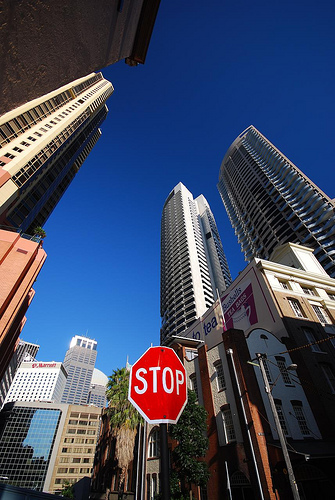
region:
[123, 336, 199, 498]
stop sign on a pole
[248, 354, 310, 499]
street light on a pole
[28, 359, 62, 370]
Marriott building in the background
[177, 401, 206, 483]
green leaves on a tree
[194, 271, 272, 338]
advertisement on a building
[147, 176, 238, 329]
skyscraper in the distance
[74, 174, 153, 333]
bright blue sky in the background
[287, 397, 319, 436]
window of a building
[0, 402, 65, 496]
glass facade of a building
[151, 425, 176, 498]
pole of a stop sign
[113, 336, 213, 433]
red stop sign on street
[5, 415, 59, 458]
reflections from black building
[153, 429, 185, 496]
black pole holding sign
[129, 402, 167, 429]
white lining of stop sign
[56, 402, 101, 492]
brown building in distance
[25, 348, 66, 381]
red marriot logo on top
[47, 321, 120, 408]
gray skyscraper in distance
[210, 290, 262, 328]
tea bag symbol on building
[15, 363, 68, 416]
white building by sign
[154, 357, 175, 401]
O on red stop sign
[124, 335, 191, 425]
A bent stop sign.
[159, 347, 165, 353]
A bolt on the sign.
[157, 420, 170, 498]
A ole for the sign.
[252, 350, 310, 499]
A street light on sidewalk.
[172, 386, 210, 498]
A tree behind sign.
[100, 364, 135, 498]
A large palm tree.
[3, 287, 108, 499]
High rise buildings.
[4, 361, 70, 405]
The Marriott hotel sticking out.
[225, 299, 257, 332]
A tea pot picture.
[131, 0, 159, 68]
A building overhang overhead.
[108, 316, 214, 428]
red and white stop sign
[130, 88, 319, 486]
very tall great buildings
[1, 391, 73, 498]
large block of windows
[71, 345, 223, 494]
a few green trees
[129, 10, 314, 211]
clear dark blue sky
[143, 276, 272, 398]
lettering on side of building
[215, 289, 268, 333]
picture of a mug on building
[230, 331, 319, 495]
tall telephone pole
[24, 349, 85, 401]
hotel label on building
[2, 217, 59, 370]
salmon colored builing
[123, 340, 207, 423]
Red and white stop sign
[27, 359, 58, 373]
Red letters spell Marriott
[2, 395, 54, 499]
Windows of building reflect other building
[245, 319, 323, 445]
White arch on building with umbrella symbol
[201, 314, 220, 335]
Blue letters spell tea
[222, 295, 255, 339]
Picture of tea cup on building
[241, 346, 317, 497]
Light post in front of building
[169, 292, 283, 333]
Advertisement is red, white and blue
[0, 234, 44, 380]
One building is tall and orange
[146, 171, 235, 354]
Tall gray and white building